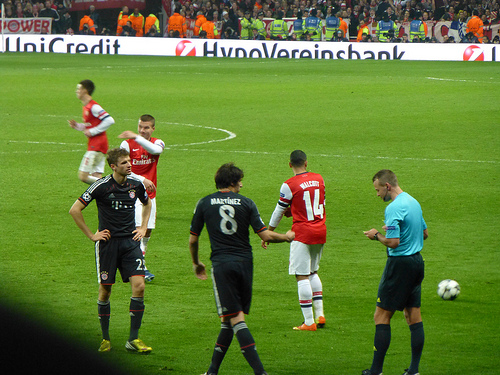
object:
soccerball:
[437, 279, 461, 300]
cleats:
[126, 351, 156, 355]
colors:
[127, 342, 151, 354]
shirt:
[269, 172, 327, 245]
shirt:
[75, 100, 114, 154]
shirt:
[117, 137, 165, 198]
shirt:
[191, 190, 269, 255]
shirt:
[76, 174, 150, 238]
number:
[302, 188, 324, 222]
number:
[219, 205, 238, 236]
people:
[77, 11, 98, 36]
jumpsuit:
[79, 15, 96, 35]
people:
[117, 10, 133, 34]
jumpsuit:
[116, 16, 134, 37]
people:
[166, 13, 217, 34]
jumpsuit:
[168, 13, 187, 38]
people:
[465, 10, 483, 40]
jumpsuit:
[465, 16, 485, 44]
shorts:
[206, 253, 256, 318]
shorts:
[95, 236, 146, 286]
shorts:
[375, 252, 425, 313]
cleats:
[312, 323, 324, 330]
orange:
[303, 326, 316, 332]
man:
[188, 163, 296, 374]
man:
[262, 150, 327, 331]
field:
[3, 52, 498, 374]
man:
[61, 151, 155, 353]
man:
[67, 79, 113, 185]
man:
[118, 115, 171, 287]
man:
[363, 170, 428, 374]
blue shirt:
[386, 191, 428, 256]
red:
[296, 199, 302, 227]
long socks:
[207, 325, 240, 375]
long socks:
[127, 296, 145, 341]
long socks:
[370, 323, 391, 375]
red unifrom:
[75, 99, 113, 174]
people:
[0, 0, 499, 45]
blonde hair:
[107, 147, 129, 170]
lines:
[4, 138, 500, 165]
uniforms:
[269, 172, 327, 332]